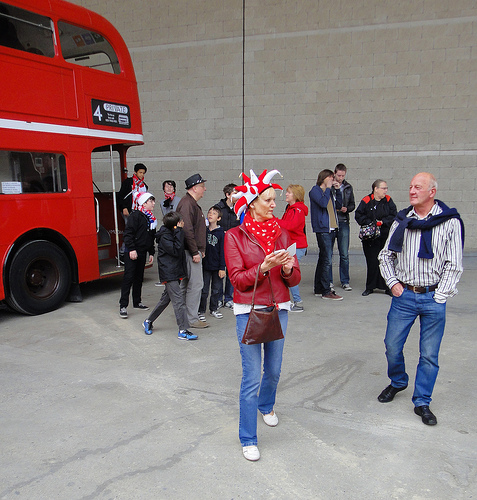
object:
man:
[376, 168, 463, 427]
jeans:
[382, 286, 447, 407]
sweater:
[384, 199, 465, 259]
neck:
[408, 203, 431, 212]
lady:
[223, 165, 299, 465]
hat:
[228, 170, 285, 219]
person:
[354, 180, 397, 299]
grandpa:
[174, 174, 208, 331]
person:
[118, 193, 155, 321]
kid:
[198, 207, 225, 321]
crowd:
[107, 165, 464, 464]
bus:
[3, 0, 142, 316]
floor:
[0, 263, 477, 499]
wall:
[73, 1, 476, 260]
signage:
[89, 99, 131, 130]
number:
[92, 104, 104, 122]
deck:
[0, 144, 147, 297]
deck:
[0, 0, 144, 141]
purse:
[240, 267, 283, 346]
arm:
[224, 234, 267, 292]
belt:
[397, 283, 436, 293]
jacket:
[222, 224, 301, 306]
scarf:
[240, 213, 282, 258]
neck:
[249, 215, 273, 229]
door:
[91, 140, 149, 279]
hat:
[179, 174, 206, 189]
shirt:
[375, 207, 463, 305]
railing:
[92, 198, 102, 232]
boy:
[140, 211, 194, 342]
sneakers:
[142, 319, 198, 342]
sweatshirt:
[276, 203, 310, 249]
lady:
[280, 183, 308, 314]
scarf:
[323, 190, 338, 229]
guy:
[307, 165, 338, 300]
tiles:
[238, 31, 475, 167]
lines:
[235, 0, 250, 184]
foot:
[238, 439, 260, 462]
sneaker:
[242, 444, 259, 460]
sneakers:
[116, 301, 148, 321]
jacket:
[353, 196, 397, 242]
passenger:
[118, 162, 152, 266]